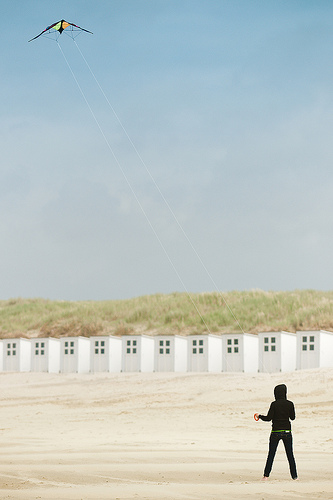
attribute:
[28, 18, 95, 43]
kite — green, flying, orange, colorful, black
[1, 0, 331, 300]
sky — blue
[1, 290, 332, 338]
grass — brown, green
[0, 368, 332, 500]
sand — golden, tan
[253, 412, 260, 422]
handle — red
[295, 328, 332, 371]
building — small, square, white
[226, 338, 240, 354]
window — small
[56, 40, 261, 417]
string — white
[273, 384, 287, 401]
hood — black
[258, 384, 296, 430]
jacket — long sleeve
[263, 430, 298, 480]
pants — black